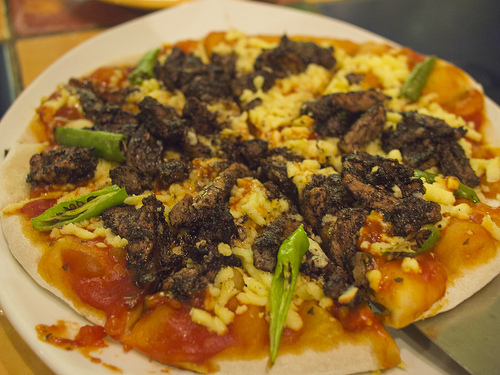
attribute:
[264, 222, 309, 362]
pepper — fresh, green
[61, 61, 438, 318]
meat — dark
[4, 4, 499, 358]
quesadilla — chicken, cheese, salsa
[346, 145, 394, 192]
meat — brown, grilled 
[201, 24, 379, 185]
pizza — round, cooked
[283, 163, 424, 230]
slice pizza — slice 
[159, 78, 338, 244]
pizza — round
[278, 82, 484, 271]
pork meat — cooked , brown-colored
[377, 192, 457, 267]
spice — Small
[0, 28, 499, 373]
pizza — taco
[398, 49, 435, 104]
pepper — green, a topping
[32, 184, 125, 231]
pepper — green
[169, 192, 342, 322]
pizza — sliced, cooked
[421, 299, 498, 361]
surface — shiny, chrome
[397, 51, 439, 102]
green pepper — topping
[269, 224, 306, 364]
pepper — green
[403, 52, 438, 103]
pepper — green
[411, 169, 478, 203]
pepper — green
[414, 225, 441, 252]
pepper — green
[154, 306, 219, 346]
salsa — tomato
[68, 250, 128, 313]
tomato sauce — Red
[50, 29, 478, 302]
beef — cooked, dark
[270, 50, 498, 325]
pepper — topping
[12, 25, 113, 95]
tile — orange , red 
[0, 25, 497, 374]
table — tiled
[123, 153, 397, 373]
slice — cut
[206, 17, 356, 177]
slice — triangular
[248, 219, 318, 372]
pepper — green, cooked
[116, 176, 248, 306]
topping — brown, meaty